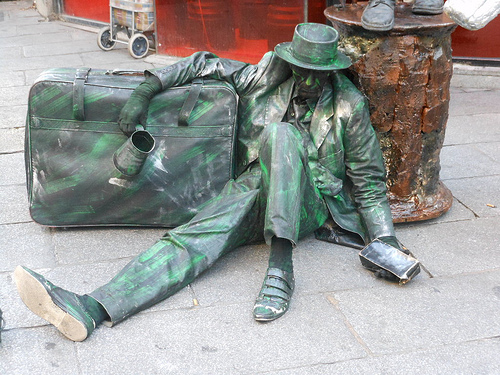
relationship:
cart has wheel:
[97, 0, 158, 61] [98, 26, 118, 52]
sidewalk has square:
[1, 1, 499, 374] [23, 39, 140, 56]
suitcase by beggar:
[26, 68, 243, 228] [10, 23, 421, 341]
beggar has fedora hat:
[10, 23, 421, 341] [274, 20, 353, 71]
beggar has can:
[10, 23, 421, 341] [112, 126, 157, 177]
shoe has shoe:
[11, 264, 98, 341] [11, 264, 98, 341]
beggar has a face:
[10, 23, 421, 341] [286, 63, 325, 98]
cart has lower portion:
[97, 0, 158, 59] [97, 5, 158, 59]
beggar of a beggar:
[10, 23, 421, 341] [10, 23, 421, 341]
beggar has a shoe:
[10, 23, 421, 341] [253, 266, 296, 320]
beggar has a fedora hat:
[10, 23, 421, 341] [274, 20, 353, 71]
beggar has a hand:
[10, 23, 421, 341] [118, 75, 161, 134]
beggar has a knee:
[10, 23, 421, 341] [259, 122, 308, 166]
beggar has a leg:
[10, 23, 421, 341] [10, 180, 265, 343]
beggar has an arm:
[10, 23, 421, 341] [119, 51, 286, 134]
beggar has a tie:
[10, 23, 421, 341] [291, 97, 311, 137]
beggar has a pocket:
[10, 23, 421, 341] [318, 150, 349, 168]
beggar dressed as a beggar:
[10, 23, 421, 341] [10, 23, 421, 341]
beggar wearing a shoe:
[10, 23, 421, 341] [253, 266, 296, 320]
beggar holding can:
[10, 23, 421, 341] [112, 126, 157, 177]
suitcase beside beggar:
[26, 68, 243, 228] [10, 23, 421, 341]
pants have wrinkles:
[85, 122, 329, 325] [162, 210, 232, 254]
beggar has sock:
[10, 23, 421, 341] [268, 234, 293, 267]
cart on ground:
[97, 0, 158, 61] [1, 0, 498, 375]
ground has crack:
[1, 0, 498, 375] [1, 148, 25, 157]